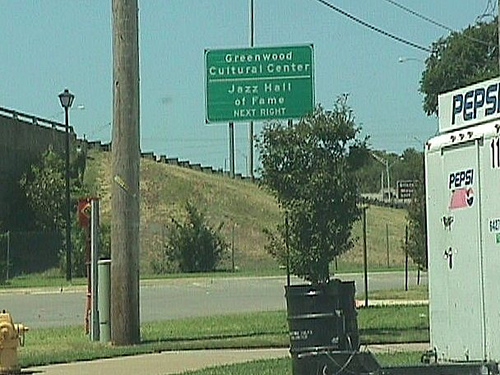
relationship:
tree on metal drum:
[253, 90, 377, 287] [279, 283, 357, 374]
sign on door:
[447, 169, 476, 214] [436, 141, 485, 365]